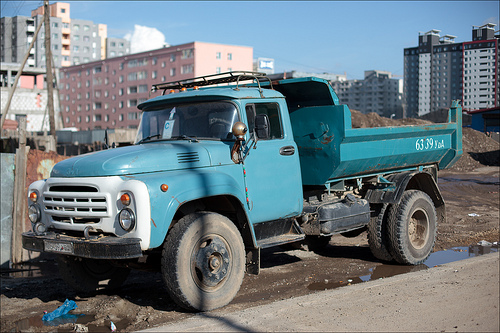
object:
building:
[55, 39, 255, 139]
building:
[401, 18, 500, 135]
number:
[415, 138, 445, 151]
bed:
[289, 83, 463, 180]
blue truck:
[22, 70, 463, 313]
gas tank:
[302, 192, 372, 236]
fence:
[0, 129, 108, 155]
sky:
[5, 0, 499, 80]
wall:
[407, 48, 497, 108]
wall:
[61, 55, 141, 125]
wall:
[9, 10, 116, 55]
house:
[57, 40, 256, 132]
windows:
[62, 71, 84, 122]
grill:
[43, 182, 112, 235]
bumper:
[21, 228, 143, 259]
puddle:
[342, 242, 499, 284]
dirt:
[4, 105, 499, 331]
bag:
[38, 297, 79, 323]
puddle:
[1, 298, 139, 332]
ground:
[0, 170, 499, 331]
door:
[239, 93, 303, 224]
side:
[125, 77, 464, 314]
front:
[22, 143, 171, 260]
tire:
[161, 211, 247, 312]